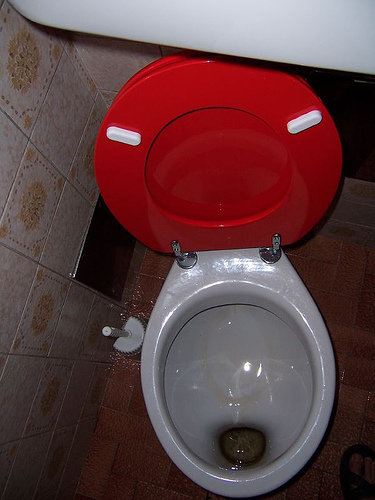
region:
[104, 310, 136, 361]
White plunger on ground.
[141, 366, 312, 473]
White bowl on toilet.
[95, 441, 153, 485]
Reddish brown tiles on the ground.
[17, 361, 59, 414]
Tan tiles on wall.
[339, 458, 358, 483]
Person wearing black sandals.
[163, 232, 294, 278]
Silver hinges on toilet seat.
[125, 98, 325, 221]
Seat on toilet is red.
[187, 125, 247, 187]
Lid on the toilet is red.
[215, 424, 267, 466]
Water inside of toilet bowl.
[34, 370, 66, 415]
Golden brown design on square tiles.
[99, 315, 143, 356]
a white toilet brush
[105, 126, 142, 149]
the left white stopper on the toilet lid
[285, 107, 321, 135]
the right white stopper on the toilet lid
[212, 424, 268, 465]
the drain in the toilet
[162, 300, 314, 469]
the toilet bowl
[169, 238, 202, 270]
the left hinge on the toilet lid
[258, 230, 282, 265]
the right hinge on the toilet lid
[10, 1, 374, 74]
a white counter top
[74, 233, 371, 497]
a brown tiled floor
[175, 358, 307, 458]
water in the toilet bowl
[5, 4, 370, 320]
this is in a restroom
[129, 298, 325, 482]
this is a toilet bowl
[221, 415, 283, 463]
the toilet is dirty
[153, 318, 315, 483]
the toilet bowl is white and brown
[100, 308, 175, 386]
this is a bowl cleaner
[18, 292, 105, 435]
the wall is tiled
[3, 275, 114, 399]
the wall is orange and white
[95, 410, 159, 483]
the ground is linoleum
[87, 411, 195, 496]
the linoleum is red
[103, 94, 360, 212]
the toilet seat is bright red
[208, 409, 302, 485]
Toilet bowl has water in it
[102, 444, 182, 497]
The floor is made of brick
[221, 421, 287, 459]
Hole in the toilet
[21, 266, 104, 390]
Wall is made of tile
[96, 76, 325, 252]
Lid on the toilet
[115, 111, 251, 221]
The toilet seat is red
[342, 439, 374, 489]
Foot on the floor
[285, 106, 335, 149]
White piece on the toilet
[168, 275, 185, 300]
The toilet is made of porcelain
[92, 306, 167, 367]
Toilet brush beside toilet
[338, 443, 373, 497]
foot with black sandal shoe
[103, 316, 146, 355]
white toilet brush in holder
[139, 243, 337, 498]
white porcelain toilet bowl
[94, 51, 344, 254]
red and white toilet seat underside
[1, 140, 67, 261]
brown and white ceramic tile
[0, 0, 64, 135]
brown and white ceramic tile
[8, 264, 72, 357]
brown and white ceramic tile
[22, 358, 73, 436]
brown and white ceramic tile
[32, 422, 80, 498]
brown and white ceramic tile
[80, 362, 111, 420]
brown and white ceramic tile